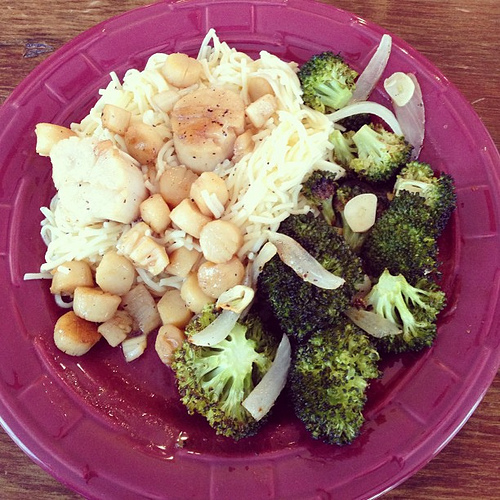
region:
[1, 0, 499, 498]
a brown wooden table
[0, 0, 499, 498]
a pink porcelain plate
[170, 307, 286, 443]
a piece of broccoli on the plate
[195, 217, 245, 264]
a brown piece of meat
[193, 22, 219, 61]
a white noodle on the plate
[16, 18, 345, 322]
a pile of noodles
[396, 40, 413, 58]
light shining on the plate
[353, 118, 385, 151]
the stem of a piece of broccoli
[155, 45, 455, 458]
a pile of broccoli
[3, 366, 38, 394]
a reflection on the plate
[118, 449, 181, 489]
a purple plate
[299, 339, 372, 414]
the brocolli is green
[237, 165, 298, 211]
white noodles on the plate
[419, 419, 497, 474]
the purple plate is on the table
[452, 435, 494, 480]
the table is brown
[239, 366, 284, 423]
white onions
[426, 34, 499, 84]
a brown table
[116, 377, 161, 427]
a reflection in the plate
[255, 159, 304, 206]
the noodles are white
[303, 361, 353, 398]
the brocolli is green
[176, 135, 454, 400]
Broccoli on the plate.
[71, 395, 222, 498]
The plate is purple.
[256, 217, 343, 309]
Onions on the broccoli.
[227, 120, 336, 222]
Noodles in the dish.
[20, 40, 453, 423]
The dish is Asian.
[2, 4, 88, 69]
The table is brown.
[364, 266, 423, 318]
Stem of the broccoli.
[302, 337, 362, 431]
The broccoli is green.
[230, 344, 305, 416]
The onion is white.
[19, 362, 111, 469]
Grooves in the plate.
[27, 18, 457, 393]
plastic plate is purple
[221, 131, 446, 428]
green broccoli on plate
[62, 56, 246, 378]
chickpeas on purple plate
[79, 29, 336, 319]
white rice on plate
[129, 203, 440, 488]
vegetables on lunch plate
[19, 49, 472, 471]
purple plate on brown table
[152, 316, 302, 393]
broccoli florets are green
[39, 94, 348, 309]
white rice with chickpeas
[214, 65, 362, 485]
sauteed onions on broccoli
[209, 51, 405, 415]
sauteed onions are white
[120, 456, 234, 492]
the plate is plastic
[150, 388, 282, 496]
the plate is plastic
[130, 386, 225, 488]
the plate is plastic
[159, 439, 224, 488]
the plate is plastic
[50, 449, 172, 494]
the plate is plastic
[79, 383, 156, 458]
the plate is plastic